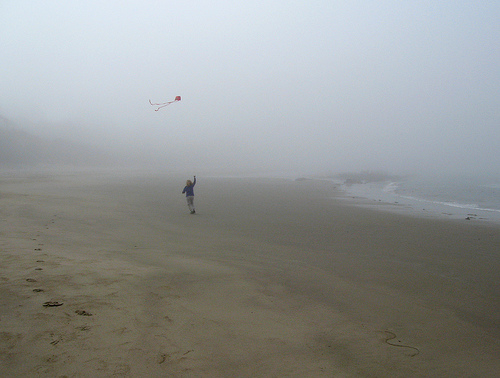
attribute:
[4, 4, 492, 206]
fog — thick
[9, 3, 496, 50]
sky — foggy, blue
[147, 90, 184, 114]
kite — red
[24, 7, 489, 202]
sky — hazy , foggy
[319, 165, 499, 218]
ocean — blue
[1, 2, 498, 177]
sky — blue, foggy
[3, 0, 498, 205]
foggy sky — blue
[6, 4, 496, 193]
sky — blue, foggy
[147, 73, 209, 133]
kite — red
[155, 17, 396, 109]
sky — foggy, blue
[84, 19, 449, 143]
sky — foggy, blue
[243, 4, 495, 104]
foggy sky — blue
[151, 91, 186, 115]
kite — red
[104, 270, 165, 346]
sand — brown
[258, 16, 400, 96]
sky — blue, foggy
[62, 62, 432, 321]
weather — foggy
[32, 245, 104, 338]
imprints — foot